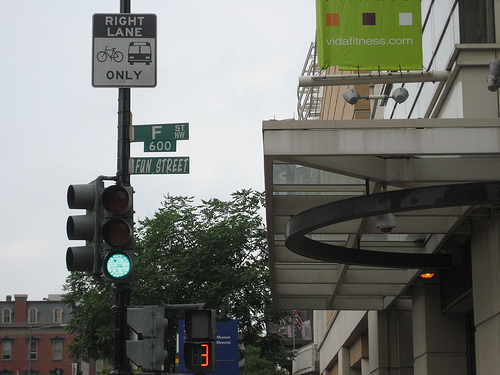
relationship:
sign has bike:
[90, 12, 156, 88] [96, 46, 124, 63]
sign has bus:
[90, 12, 156, 88] [130, 40, 154, 65]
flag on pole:
[295, 308, 304, 328] [291, 311, 296, 351]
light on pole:
[100, 185, 134, 287] [117, 90, 130, 183]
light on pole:
[63, 182, 93, 273] [117, 90, 130, 183]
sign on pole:
[90, 12, 156, 88] [117, 90, 130, 183]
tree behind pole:
[138, 218, 266, 298] [117, 90, 130, 183]